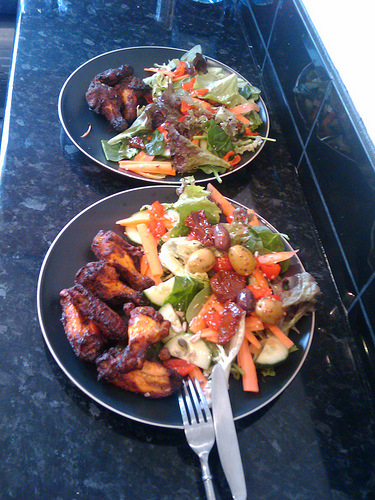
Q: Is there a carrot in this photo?
A: Yes, there is a carrot.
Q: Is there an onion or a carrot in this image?
A: Yes, there is a carrot.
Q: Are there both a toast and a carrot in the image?
A: No, there is a carrot but no toasts.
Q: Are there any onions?
A: No, there are no onions.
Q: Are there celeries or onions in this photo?
A: No, there are no onions or celeries.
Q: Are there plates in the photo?
A: Yes, there is a plate.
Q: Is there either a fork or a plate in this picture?
A: Yes, there is a plate.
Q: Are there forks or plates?
A: Yes, there is a plate.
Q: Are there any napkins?
A: No, there are no napkins.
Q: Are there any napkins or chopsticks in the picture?
A: No, there are no napkins or chopsticks.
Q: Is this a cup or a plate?
A: This is a plate.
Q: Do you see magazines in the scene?
A: No, there are no magazines.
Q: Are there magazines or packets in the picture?
A: No, there are no magazines or packets.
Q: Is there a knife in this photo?
A: Yes, there is a knife.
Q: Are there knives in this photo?
A: Yes, there is a knife.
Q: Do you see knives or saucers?
A: Yes, there is a knife.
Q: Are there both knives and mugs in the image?
A: No, there is a knife but no mugs.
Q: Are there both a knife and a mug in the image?
A: No, there is a knife but no mugs.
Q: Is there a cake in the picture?
A: No, there are no cakes.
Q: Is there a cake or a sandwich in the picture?
A: No, there are no cakes or sandwiches.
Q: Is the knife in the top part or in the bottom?
A: The knife is in the bottom of the image.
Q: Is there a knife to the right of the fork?
A: Yes, there is a knife to the right of the fork.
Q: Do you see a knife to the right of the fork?
A: Yes, there is a knife to the right of the fork.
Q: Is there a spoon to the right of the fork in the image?
A: No, there is a knife to the right of the fork.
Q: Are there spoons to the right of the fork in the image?
A: No, there is a knife to the right of the fork.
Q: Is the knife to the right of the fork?
A: Yes, the knife is to the right of the fork.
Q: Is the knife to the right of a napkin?
A: No, the knife is to the right of the fork.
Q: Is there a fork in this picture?
A: Yes, there is a fork.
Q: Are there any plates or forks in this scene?
A: Yes, there is a fork.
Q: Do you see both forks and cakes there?
A: No, there is a fork but no cakes.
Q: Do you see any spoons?
A: No, there are no spoons.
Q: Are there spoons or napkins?
A: No, there are no spoons or napkins.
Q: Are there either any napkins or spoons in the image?
A: No, there are no spoons or napkins.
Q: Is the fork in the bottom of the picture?
A: Yes, the fork is in the bottom of the image.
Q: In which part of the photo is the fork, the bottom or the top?
A: The fork is in the bottom of the image.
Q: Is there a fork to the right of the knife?
A: No, the fork is to the left of the knife.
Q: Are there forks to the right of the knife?
A: No, the fork is to the left of the knife.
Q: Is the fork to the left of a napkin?
A: No, the fork is to the left of a knife.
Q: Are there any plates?
A: Yes, there is a plate.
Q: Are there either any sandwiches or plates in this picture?
A: Yes, there is a plate.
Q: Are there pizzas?
A: No, there are no pizzas.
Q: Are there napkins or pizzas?
A: No, there are no pizzas or napkins.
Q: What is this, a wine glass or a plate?
A: This is a plate.